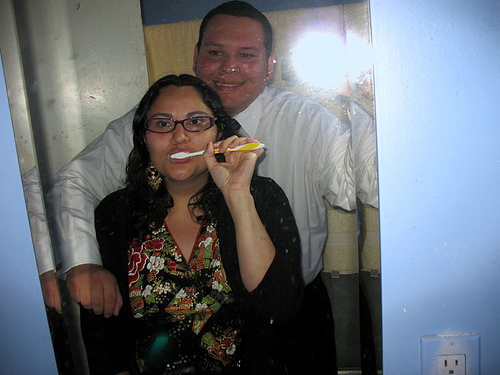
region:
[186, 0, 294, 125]
man with very short dark hair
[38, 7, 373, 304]
man wearing long sleeve dress shirt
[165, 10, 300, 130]
man with a very large smile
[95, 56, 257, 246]
woman with long dark brown hair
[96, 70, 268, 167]
woman wearing dark rim glasses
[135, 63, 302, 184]
woman using a yellow and white toothbrush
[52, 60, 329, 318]
woman wearing a black sweater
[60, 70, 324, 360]
woman wearing floral shirt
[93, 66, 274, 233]
woman with long gold earrings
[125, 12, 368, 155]
reflection of camera in the picture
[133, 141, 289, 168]
Woman is brushing her teeth.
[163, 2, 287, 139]
Man is standing behind her.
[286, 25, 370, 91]
Flash from the camera.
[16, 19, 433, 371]
Picture is a selfie taken in the mirror.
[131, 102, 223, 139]
Woman is wearing glasses.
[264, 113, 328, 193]
He is wearing a white dress shirt.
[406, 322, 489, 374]
Outlet on the wall.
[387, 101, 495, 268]
The wall is blue.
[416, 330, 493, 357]
Paint on the outlet.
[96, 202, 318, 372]
Woman is wearing a black jacket over dress.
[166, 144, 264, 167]
the girl has a toothbrush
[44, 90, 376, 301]
the man is wearing a shirt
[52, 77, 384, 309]
the shirt is white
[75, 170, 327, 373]
the girl is wearing a sweater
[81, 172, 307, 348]
the sweater is black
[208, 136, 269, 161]
the toothbrush has a yellow stripe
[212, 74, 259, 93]
the man is smiling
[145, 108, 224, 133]
the girl is wearing glasses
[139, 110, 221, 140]
the glasses are black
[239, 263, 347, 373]
the man is wearing black pants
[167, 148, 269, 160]
Toothbrush with the girl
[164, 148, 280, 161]
Yellow toothbrush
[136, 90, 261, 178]
Girl with glasses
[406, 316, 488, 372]
Electric outlet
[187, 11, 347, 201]
Man in the mirror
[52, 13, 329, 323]
A man and women in the mirror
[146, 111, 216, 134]
Ladies glasses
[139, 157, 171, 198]
earrings the women is wearing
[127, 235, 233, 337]
Flower shirt for the women who is brushing her teeth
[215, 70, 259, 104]
Smiling face of the man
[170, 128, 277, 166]
YELLOW AND WHITE TOOTHBRUSH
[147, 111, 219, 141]
BLACK RIMMED GLASSES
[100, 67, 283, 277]
LADY BRUSHING HER TEETH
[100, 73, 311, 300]
LADY HOLDING TOOTHBRUSH IN MOUTH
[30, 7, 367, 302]
MAN STANDING BEHIND LADY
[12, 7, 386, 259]
MAN SMILING BEHIND LADY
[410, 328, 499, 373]
ELECTRICAL OUTLET PLATE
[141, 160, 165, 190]
LADY WEARING GOLD EARRING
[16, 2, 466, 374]
LADY AND MAN STANDING IN FRONT OF MIRROR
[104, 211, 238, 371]
LADY WEARING FLORAL BLOUSE